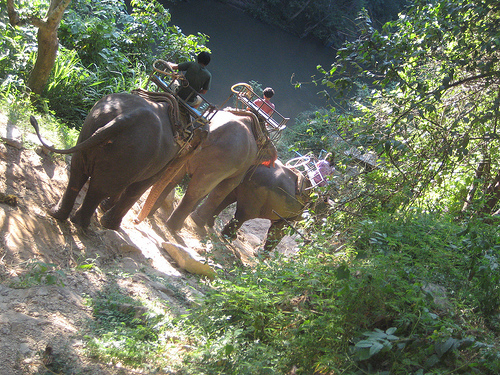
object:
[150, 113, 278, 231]
elephants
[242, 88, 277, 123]
passengers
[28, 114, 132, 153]
tail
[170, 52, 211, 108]
man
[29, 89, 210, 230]
elephant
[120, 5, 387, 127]
river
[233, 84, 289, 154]
chairs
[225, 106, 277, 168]
blankets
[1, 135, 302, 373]
dirt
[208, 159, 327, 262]
elephant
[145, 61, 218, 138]
chair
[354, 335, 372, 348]
leaves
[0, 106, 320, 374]
ground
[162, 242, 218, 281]
rocks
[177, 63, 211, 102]
shirt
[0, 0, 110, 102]
trees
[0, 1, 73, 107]
trunk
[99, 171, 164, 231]
legs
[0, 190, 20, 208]
feces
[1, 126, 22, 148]
rock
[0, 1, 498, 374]
greenery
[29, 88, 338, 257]
row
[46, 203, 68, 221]
foot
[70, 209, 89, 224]
foot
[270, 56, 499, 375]
woods